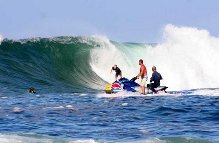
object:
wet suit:
[109, 67, 121, 75]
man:
[109, 64, 123, 80]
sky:
[0, 0, 219, 43]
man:
[135, 59, 148, 95]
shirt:
[150, 73, 163, 84]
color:
[106, 40, 149, 55]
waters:
[0, 24, 219, 143]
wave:
[139, 95, 188, 112]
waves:
[0, 25, 219, 90]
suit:
[148, 72, 163, 91]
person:
[26, 87, 38, 95]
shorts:
[140, 78, 149, 87]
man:
[146, 66, 162, 93]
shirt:
[111, 67, 121, 76]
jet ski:
[118, 77, 168, 93]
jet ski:
[104, 75, 121, 94]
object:
[20, 81, 58, 101]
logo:
[110, 82, 123, 90]